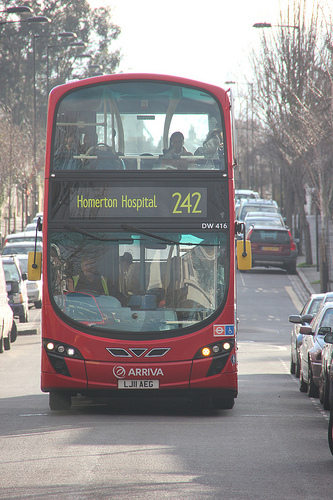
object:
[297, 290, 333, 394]
cars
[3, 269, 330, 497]
street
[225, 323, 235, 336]
handicap symbol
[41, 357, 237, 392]
plate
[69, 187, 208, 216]
sign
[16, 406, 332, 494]
picture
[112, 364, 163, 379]
manufacturer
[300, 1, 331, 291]
trees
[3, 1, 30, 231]
trees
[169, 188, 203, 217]
242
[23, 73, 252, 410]
bus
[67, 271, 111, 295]
safety vest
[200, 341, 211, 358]
lights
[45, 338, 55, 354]
lights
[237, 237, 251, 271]
mirror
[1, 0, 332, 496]
city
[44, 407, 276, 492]
asphalt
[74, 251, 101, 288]
driver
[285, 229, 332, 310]
sidewalk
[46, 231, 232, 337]
windshield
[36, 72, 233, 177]
level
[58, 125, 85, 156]
passenger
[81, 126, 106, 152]
passenger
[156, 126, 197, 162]
passenger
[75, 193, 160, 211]
letters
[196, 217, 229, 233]
sign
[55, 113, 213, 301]
people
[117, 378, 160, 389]
license plate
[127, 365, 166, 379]
arriva